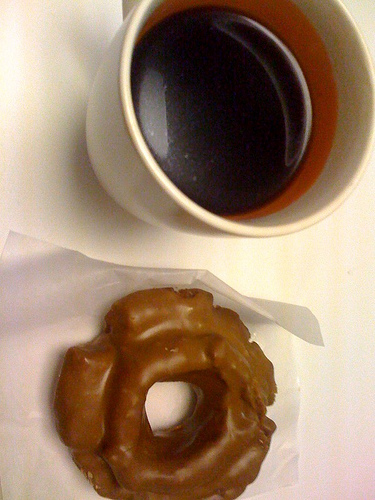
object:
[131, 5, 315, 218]
liquid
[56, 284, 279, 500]
chocolate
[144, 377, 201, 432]
hole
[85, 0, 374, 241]
cup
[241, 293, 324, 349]
corner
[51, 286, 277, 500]
food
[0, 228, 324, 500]
paper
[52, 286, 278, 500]
donut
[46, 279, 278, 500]
item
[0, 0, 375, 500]
surface